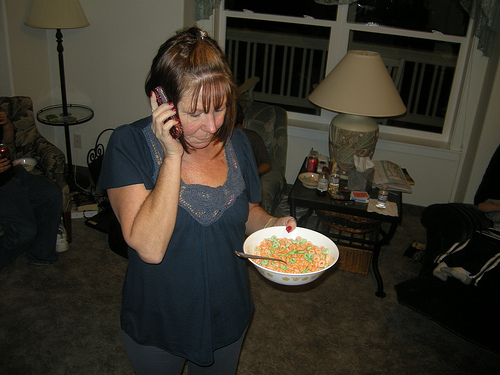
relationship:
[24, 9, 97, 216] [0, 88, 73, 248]
floor lamp by chair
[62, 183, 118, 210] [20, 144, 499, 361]
book on floor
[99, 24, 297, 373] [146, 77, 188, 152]
woman holding cell phone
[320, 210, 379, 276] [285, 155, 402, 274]
basket under table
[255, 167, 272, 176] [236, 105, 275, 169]
arm on man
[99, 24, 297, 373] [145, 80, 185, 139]
woman talking on phone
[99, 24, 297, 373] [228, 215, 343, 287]
woman holding bowl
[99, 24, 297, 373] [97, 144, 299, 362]
woman in shirt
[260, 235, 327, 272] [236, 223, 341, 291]
cereal in bowl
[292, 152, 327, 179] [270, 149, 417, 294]
can on table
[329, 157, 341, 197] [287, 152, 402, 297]
water bottle on table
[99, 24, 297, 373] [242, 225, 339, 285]
woman holding bowl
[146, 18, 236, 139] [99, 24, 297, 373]
hair on woman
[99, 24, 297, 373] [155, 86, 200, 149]
woman on phone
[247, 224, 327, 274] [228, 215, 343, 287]
cereal in bowl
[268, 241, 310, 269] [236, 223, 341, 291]
cereal in bowl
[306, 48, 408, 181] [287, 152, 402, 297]
lamp sitting on table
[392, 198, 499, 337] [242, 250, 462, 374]
chair sitting on carpet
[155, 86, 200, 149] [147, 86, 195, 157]
phone in hand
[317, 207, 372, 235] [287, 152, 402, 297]
basket under table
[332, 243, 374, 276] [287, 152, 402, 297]
basket under table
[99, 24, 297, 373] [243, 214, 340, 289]
woman holding bowl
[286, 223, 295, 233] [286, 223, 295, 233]
nail polish on nail polish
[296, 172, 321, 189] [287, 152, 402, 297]
bowl on table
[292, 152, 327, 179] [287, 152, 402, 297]
can on table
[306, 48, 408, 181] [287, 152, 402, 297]
lamp on table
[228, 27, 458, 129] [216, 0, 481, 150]
wooden fence outside window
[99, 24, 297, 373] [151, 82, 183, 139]
woman talking on phone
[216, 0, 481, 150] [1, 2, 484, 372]
window adorning home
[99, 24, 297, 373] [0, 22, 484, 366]
woman standing in foreground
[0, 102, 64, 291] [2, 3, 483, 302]
person sitting in background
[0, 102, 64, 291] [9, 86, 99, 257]
person sitting in chair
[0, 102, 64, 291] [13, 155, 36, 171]
person eating cereal